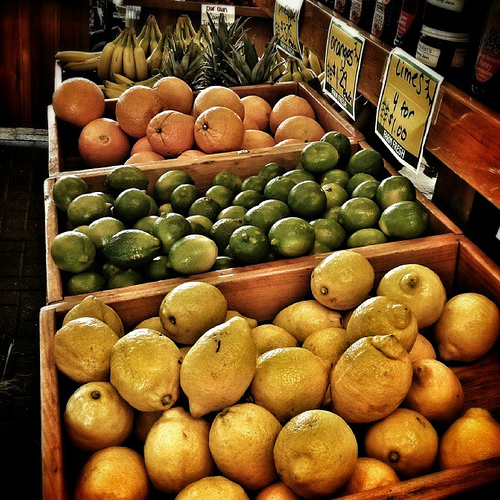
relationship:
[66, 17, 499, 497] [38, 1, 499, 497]
fruit in bins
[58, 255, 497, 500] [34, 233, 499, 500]
lemons in bin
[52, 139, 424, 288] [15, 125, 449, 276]
limes in bin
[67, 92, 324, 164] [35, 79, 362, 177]
oranges in bin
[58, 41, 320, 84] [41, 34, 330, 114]
tropical fruit in bin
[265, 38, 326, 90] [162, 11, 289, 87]
bananas behind pineapples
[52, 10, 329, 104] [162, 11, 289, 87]
bananas share space with pineapples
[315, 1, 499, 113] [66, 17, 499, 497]
condiments above behind fruit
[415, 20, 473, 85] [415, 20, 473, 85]
condiments in condiments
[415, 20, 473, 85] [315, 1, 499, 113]
condiments amid condiments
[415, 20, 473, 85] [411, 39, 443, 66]
condiments has label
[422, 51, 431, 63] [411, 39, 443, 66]
word 'jam' on label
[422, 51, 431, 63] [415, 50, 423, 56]
word 'jam' preceded by word fragm '…erry'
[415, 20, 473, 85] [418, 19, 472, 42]
condiments has lid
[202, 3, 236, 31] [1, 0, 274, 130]
sign at back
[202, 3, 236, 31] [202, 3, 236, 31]
sign advertises sign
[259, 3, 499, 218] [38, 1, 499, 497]
shelf behind bins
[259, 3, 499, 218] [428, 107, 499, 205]
shelf has a few scuffs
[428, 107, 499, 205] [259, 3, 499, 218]
scuffs in shelf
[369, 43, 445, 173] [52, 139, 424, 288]
sign above limes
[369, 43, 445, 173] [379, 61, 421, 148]
sign says 'limes 4 for $1.00'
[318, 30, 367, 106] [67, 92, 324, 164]
sign above oranges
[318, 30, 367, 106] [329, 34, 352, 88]
sign says 'oranges $1.29'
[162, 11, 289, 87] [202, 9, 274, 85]
pineapples have leaves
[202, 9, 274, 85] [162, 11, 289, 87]
leaves are all visible of pineapples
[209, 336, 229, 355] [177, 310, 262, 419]
line on lemon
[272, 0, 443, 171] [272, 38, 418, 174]
signs all say 'farm fresh'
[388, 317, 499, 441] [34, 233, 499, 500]
bottom of bin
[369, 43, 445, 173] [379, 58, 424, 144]
sign has 'limes 4 for $1.00'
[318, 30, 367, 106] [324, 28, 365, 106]
sign has handwritten info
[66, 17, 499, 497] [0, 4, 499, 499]
fruit for sale in 'farm fresh'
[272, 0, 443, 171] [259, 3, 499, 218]
signs taped to shelf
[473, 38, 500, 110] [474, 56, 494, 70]
honey of honey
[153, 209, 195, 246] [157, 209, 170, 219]
lime has bump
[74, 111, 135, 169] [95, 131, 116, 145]
orange has navel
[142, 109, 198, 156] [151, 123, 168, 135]
orange has stem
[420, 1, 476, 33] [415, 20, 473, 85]
jar atop condiments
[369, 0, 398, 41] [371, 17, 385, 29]
jar has sauce